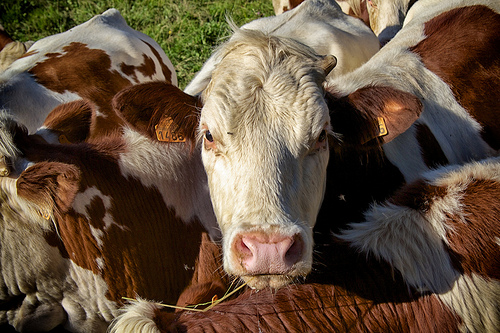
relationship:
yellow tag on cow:
[149, 109, 189, 145] [112, 22, 430, 292]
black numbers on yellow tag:
[155, 127, 185, 140] [149, 111, 189, 145]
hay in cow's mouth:
[140, 280, 239, 310] [221, 267, 306, 287]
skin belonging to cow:
[21, 38, 130, 126] [0, 6, 179, 133]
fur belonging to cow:
[196, 12, 331, 292] [110, 0, 485, 291]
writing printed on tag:
[157, 128, 184, 142] [151, 110, 187, 145]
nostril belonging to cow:
[230, 233, 254, 265] [110, 0, 485, 291]